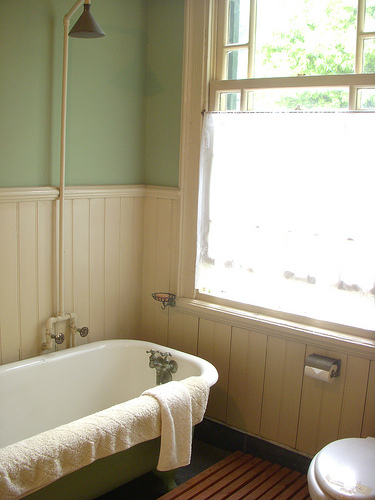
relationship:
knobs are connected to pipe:
[44, 321, 97, 346] [25, 197, 95, 327]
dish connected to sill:
[145, 291, 198, 325] [179, 285, 224, 333]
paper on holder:
[277, 349, 350, 390] [304, 353, 344, 374]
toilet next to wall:
[301, 406, 374, 499] [90, 62, 154, 145]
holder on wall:
[304, 353, 344, 374] [90, 62, 154, 145]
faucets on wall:
[149, 347, 183, 379] [90, 62, 154, 145]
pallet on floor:
[201, 456, 300, 497] [141, 448, 355, 499]